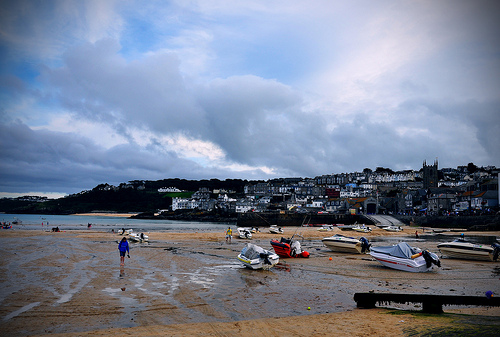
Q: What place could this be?
A: It is a shore.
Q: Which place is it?
A: It is a shore.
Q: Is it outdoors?
A: Yes, it is outdoors.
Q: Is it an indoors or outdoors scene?
A: It is outdoors.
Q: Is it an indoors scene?
A: No, it is outdoors.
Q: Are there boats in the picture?
A: Yes, there is a boat.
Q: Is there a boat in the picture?
A: Yes, there is a boat.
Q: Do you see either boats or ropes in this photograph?
A: Yes, there is a boat.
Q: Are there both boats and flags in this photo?
A: No, there is a boat but no flags.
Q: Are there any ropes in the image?
A: No, there are no ropes.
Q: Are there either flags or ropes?
A: No, there are no ropes or flags.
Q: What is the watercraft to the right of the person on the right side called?
A: The watercraft is a boat.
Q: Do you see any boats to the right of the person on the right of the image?
A: Yes, there is a boat to the right of the person.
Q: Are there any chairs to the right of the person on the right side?
A: No, there is a boat to the right of the person.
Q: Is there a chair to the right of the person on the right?
A: No, there is a boat to the right of the person.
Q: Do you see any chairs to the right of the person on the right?
A: No, there is a boat to the right of the person.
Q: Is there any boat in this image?
A: Yes, there is a boat.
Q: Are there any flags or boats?
A: Yes, there is a boat.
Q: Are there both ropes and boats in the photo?
A: No, there is a boat but no ropes.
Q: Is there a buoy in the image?
A: No, there are no buoys.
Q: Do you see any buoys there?
A: No, there are no buoys.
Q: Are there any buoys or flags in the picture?
A: No, there are no buoys or flags.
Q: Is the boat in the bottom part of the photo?
A: Yes, the boat is in the bottom of the image.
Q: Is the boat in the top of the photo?
A: No, the boat is in the bottom of the image.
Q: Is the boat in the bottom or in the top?
A: The boat is in the bottom of the image.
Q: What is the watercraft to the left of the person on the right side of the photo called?
A: The watercraft is a boat.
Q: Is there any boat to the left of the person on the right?
A: Yes, there is a boat to the left of the person.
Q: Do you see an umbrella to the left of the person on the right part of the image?
A: No, there is a boat to the left of the person.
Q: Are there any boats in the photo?
A: Yes, there is a boat.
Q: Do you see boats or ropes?
A: Yes, there is a boat.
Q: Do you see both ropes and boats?
A: No, there is a boat but no ropes.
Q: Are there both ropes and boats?
A: No, there is a boat but no ropes.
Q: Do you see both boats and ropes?
A: No, there is a boat but no ropes.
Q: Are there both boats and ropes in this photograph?
A: No, there is a boat but no ropes.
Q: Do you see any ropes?
A: No, there are no ropes.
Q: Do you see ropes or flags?
A: No, there are no ropes or flags.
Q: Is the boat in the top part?
A: No, the boat is in the bottom of the image.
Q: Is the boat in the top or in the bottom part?
A: The boat is in the bottom of the image.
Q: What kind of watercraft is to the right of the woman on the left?
A: The watercraft is a boat.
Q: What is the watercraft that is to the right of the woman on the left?
A: The watercraft is a boat.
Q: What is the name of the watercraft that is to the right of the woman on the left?
A: The watercraft is a boat.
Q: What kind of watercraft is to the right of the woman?
A: The watercraft is a boat.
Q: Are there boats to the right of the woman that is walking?
A: Yes, there is a boat to the right of the woman.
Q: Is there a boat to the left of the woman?
A: No, the boat is to the right of the woman.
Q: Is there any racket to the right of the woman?
A: No, there is a boat to the right of the woman.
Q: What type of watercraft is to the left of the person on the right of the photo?
A: The watercraft is a boat.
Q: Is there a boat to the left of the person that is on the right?
A: Yes, there is a boat to the left of the person.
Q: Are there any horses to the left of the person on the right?
A: No, there is a boat to the left of the person.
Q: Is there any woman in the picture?
A: Yes, there is a woman.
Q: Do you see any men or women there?
A: Yes, there is a woman.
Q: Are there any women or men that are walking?
A: Yes, the woman is walking.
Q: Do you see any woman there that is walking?
A: Yes, there is a woman that is walking.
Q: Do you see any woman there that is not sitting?
A: Yes, there is a woman that is walking .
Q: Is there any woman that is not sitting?
A: Yes, there is a woman that is walking.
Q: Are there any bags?
A: No, there are no bags.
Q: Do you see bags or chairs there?
A: No, there are no bags or chairs.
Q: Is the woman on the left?
A: Yes, the woman is on the left of the image.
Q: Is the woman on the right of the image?
A: No, the woman is on the left of the image.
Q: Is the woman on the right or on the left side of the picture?
A: The woman is on the left of the image.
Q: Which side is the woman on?
A: The woman is on the left of the image.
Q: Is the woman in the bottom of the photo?
A: Yes, the woman is in the bottom of the image.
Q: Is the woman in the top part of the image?
A: No, the woman is in the bottom of the image.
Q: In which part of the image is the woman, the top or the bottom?
A: The woman is in the bottom of the image.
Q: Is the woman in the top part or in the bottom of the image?
A: The woman is in the bottom of the image.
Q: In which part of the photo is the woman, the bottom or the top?
A: The woman is in the bottom of the image.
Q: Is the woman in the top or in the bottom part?
A: The woman is in the bottom of the image.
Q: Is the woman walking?
A: Yes, the woman is walking.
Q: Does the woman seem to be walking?
A: Yes, the woman is walking.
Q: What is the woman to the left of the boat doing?
A: The woman is walking.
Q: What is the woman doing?
A: The woman is walking.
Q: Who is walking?
A: The woman is walking.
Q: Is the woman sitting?
A: No, the woman is walking.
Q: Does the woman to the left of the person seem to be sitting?
A: No, the woman is walking.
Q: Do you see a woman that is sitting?
A: No, there is a woman but she is walking.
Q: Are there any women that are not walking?
A: No, there is a woman but she is walking.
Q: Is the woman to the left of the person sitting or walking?
A: The woman is walking.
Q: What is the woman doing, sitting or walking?
A: The woman is walking.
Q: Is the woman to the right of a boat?
A: No, the woman is to the left of a boat.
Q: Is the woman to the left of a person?
A: Yes, the woman is to the left of a person.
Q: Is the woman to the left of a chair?
A: No, the woman is to the left of a person.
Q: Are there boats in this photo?
A: Yes, there is a boat.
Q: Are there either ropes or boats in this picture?
A: Yes, there is a boat.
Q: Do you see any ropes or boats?
A: Yes, there is a boat.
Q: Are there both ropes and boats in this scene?
A: No, there is a boat but no ropes.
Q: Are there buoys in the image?
A: No, there are no buoys.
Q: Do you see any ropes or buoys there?
A: No, there are no buoys or ropes.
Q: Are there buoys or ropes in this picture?
A: No, there are no buoys or ropes.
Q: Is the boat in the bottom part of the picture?
A: Yes, the boat is in the bottom of the image.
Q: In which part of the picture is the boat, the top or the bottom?
A: The boat is in the bottom of the image.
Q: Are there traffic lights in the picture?
A: No, there are no traffic lights.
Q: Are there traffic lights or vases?
A: No, there are no traffic lights or vases.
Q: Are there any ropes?
A: No, there are no ropes.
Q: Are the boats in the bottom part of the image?
A: Yes, the boats are in the bottom of the image.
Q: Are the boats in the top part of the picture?
A: No, the boats are in the bottom of the image.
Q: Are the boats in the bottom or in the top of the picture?
A: The boats are in the bottom of the image.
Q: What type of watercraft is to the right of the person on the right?
A: The watercraft is boats.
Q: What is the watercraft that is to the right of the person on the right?
A: The watercraft is boats.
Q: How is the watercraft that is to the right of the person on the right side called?
A: The watercraft is boats.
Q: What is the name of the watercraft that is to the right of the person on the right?
A: The watercraft is boats.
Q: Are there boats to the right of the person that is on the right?
A: Yes, there are boats to the right of the person.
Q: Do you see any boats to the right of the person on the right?
A: Yes, there are boats to the right of the person.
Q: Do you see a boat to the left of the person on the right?
A: No, the boats are to the right of the person.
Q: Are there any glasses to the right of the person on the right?
A: No, there are boats to the right of the person.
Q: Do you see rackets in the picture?
A: No, there are no rackets.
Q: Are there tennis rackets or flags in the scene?
A: No, there are no tennis rackets or flags.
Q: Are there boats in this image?
A: Yes, there is a boat.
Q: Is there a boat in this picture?
A: Yes, there is a boat.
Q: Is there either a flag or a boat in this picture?
A: Yes, there is a boat.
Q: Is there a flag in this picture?
A: No, there are no flags.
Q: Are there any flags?
A: No, there are no flags.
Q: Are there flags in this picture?
A: No, there are no flags.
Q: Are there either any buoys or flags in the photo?
A: No, there are no flags or buoys.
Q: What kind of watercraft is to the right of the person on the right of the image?
A: The watercraft is a boat.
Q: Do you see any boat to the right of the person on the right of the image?
A: Yes, there is a boat to the right of the person.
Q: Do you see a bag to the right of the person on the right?
A: No, there is a boat to the right of the person.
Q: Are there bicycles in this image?
A: No, there are no bicycles.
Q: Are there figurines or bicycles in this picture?
A: No, there are no bicycles or figurines.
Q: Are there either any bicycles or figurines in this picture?
A: No, there are no bicycles or figurines.